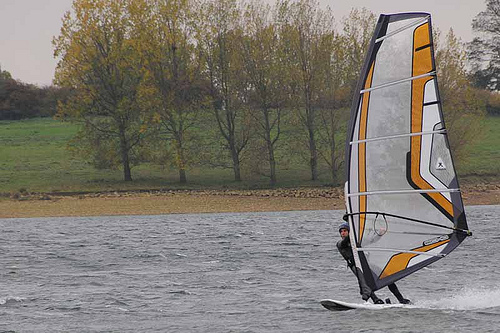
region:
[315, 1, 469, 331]
the man is parasailing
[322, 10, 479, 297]
parasail is black white and orange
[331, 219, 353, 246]
man wearing a helmet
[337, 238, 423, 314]
man wearing a wet suit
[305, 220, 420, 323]
man standing on surf board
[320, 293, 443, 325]
the surfboard is white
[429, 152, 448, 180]
triangle on the parasail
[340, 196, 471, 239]
black cord on the parasail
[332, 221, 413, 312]
man standing behind the parasail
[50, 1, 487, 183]
trees on side of water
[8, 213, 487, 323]
water near a land area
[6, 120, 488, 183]
green space in park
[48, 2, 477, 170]
trees along the green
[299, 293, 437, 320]
board person is standing on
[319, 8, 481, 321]
person on board with sail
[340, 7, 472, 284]
sail on the board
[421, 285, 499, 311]
water propelling from board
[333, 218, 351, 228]
hat on the person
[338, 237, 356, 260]
jacket on the person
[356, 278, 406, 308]
pants on the surfer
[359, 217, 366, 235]
orange fabric on water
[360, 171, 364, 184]
orange fabric on water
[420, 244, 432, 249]
orange fabric on water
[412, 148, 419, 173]
orange fabric on water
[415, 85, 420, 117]
orange fabric on water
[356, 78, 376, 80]
orange fabric on water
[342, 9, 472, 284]
white and orange sail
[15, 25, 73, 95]
white clouds in blue sky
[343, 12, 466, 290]
yellow and gray wind surf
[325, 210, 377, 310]
person hold onto the kite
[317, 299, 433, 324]
feet on surfboard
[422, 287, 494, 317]
splash from the surfboard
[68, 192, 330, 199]
rocks on the beach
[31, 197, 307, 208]
beach is filled with sand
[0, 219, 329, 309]
water is calm and blue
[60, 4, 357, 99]
yellow leaves on the trees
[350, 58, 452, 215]
wind surf is tied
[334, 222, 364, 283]
man in dark swim suit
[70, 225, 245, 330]
a body of water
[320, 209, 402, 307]
a man boarding on a body of water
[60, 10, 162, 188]
A tree in the woods.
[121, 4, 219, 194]
A tree in the woods.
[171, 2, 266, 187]
A tree in the woods.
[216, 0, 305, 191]
A tree in the woods.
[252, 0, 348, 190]
A tree in the woods.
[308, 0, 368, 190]
A tree in the woods.